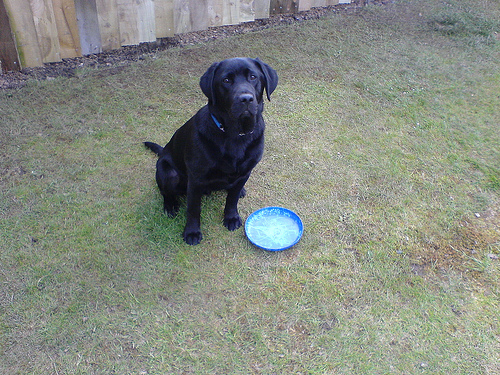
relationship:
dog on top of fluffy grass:
[140, 54, 277, 244] [0, 0, 499, 375]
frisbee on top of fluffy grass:
[244, 206, 303, 252] [0, 0, 499, 375]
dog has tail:
[140, 54, 277, 244] [143, 139, 165, 156]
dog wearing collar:
[140, 54, 277, 244] [207, 109, 254, 138]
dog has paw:
[140, 54, 277, 244] [182, 223, 204, 245]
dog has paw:
[140, 54, 277, 244] [222, 210, 243, 232]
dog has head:
[140, 54, 277, 244] [199, 55, 280, 133]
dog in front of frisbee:
[140, 54, 277, 244] [244, 206, 303, 252]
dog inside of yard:
[140, 54, 277, 244] [1, 0, 499, 373]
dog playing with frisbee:
[140, 54, 277, 244] [244, 206, 303, 252]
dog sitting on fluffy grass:
[140, 54, 277, 244] [0, 0, 499, 375]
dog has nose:
[140, 54, 277, 244] [238, 93, 256, 104]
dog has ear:
[140, 54, 277, 244] [197, 60, 221, 103]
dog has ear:
[140, 54, 277, 244] [251, 56, 280, 103]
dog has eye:
[140, 54, 277, 244] [248, 72, 258, 80]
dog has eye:
[140, 54, 277, 244] [221, 75, 231, 83]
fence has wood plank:
[0, 0, 355, 73] [73, 1, 103, 57]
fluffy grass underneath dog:
[145, 186, 215, 254] [140, 54, 277, 244]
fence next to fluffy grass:
[0, 0, 355, 73] [0, 0, 499, 375]